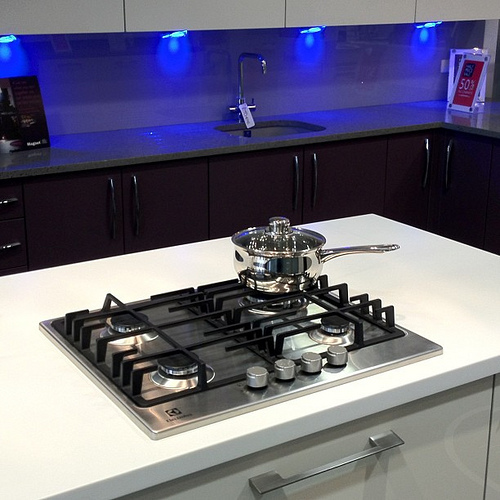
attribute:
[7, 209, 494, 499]
kitchen island — white, gray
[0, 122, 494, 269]
cabinets — brown, dark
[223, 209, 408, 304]
pan — shiny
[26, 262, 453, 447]
stove — gas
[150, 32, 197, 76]
light — blue, glowing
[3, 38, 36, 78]
light — blue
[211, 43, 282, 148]
faucet — unusually fashioned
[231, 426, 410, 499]
handle — fashionable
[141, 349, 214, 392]
burner — round